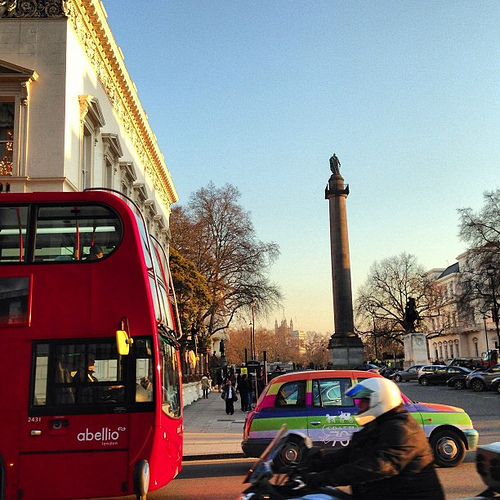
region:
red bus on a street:
[1, 166, 193, 498]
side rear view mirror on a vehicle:
[106, 311, 142, 360]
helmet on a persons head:
[338, 368, 409, 433]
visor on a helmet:
[338, 379, 377, 403]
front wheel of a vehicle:
[424, 418, 471, 471]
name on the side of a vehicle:
[68, 423, 129, 450]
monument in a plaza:
[308, 142, 382, 377]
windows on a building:
[427, 336, 462, 363]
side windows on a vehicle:
[271, 374, 357, 411]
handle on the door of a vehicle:
[306, 415, 326, 431]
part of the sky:
[265, 2, 319, 41]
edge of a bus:
[132, 379, 162, 464]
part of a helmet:
[347, 355, 392, 425]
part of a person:
[213, 386, 231, 418]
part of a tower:
[330, 325, 360, 345]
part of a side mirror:
[108, 310, 131, 397]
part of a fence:
[165, 359, 205, 406]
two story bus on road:
[4, 172, 187, 497]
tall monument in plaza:
[317, 138, 391, 379]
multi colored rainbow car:
[210, 354, 497, 476]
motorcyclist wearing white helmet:
[313, 369, 428, 439]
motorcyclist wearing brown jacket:
[276, 367, 463, 495]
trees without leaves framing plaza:
[163, 171, 301, 418]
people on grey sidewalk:
[207, 360, 267, 417]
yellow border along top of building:
[27, 1, 230, 223]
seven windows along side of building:
[75, 88, 190, 272]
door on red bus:
[20, 322, 155, 497]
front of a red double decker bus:
[2, 192, 190, 497]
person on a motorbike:
[231, 378, 448, 499]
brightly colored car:
[234, 363, 484, 470]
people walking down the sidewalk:
[200, 362, 256, 415]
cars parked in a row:
[392, 354, 499, 395]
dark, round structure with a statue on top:
[321, 151, 363, 351]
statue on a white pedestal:
[398, 293, 433, 361]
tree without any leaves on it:
[456, 191, 498, 346]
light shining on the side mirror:
[113, 322, 138, 359]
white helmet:
[343, 377, 405, 427]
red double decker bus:
[2, 169, 195, 495]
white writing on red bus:
[19, 332, 156, 477]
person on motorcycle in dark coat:
[236, 383, 471, 493]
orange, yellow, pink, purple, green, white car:
[262, 367, 465, 440]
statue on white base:
[389, 291, 469, 394]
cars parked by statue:
[393, 351, 495, 412]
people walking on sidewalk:
[209, 363, 252, 414]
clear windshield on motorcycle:
[229, 412, 333, 499]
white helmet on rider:
[332, 378, 438, 487]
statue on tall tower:
[311, 142, 400, 363]